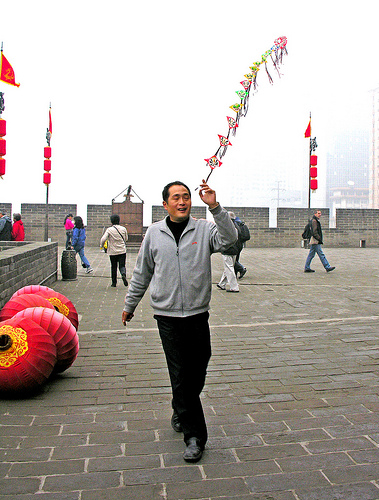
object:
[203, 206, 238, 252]
arm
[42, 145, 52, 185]
lanterns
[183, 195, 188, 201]
eye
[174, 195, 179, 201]
eye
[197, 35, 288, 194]
kite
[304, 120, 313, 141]
flag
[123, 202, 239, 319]
sweater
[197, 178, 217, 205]
hand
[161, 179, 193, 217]
head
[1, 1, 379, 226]
sky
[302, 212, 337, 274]
man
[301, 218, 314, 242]
backpack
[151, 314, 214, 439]
pants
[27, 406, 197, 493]
lines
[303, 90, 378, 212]
buildings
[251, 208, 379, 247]
wall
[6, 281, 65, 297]
paper lantern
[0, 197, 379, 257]
building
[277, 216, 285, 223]
brick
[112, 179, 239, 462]
he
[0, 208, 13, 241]
people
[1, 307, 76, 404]
lantern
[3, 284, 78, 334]
lantern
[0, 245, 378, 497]
ground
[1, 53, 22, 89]
flag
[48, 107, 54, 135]
flag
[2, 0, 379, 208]
clouds